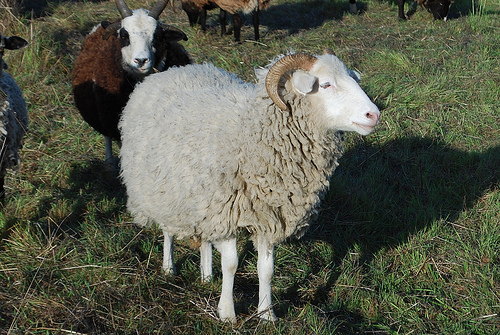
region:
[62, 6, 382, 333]
two sheep in a pasture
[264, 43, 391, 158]
the head of a sheep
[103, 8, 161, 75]
the head of a sheep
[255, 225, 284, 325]
the leg of a sheep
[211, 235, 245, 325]
the leg of a sheep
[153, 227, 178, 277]
the leg of a sheep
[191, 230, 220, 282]
the leg of a sheep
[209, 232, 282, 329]
the front legs of a sheep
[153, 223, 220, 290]
the rear legs of a sheep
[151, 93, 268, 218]
the fur of a sheep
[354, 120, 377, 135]
a rams mouth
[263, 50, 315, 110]
a single ram horn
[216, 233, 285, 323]
a pair of white front legs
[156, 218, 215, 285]
a pair of back legs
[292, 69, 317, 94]
a white ram ear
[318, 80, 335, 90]
a ram eye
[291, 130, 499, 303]
the shadow of a ram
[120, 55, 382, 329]
a white ram with a dirty coat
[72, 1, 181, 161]
a brown fluffy ram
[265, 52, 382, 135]
the head of a ram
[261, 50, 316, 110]
a single rams horn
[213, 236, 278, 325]
a white pair of front legs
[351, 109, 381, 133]
the nose and mouth of a ram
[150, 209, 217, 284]
a back pair of legs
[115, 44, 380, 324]
a white dirty ram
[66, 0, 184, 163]
a dark brown ram with a white head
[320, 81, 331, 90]
a rams eye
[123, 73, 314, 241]
the white coat of a ram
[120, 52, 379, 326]
white sheep with curved brown horns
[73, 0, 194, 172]
brown, black and white sheep with horns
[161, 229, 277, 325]
sheep's legs sticking out from wool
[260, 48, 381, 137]
ship's head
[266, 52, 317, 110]
brown sheep's horn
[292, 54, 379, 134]
sheep's face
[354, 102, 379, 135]
sheep's nose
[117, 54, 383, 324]
wooly sheep ready to be sheared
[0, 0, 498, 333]
flock of sheep in grassy field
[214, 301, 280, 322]
sheep hooves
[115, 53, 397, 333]
white sheep standing in the grass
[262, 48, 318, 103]
horn of the white sheep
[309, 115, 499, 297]
shadow of the white sheep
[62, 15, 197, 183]
brown sheep with white face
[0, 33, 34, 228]
sheep standing on the left side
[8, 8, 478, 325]
grass pasture the sheep are in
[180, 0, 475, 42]
black legs of sheep in the background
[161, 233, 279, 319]
white legs of sheep in the foreground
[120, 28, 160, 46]
brown markings on white face of sheep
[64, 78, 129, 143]
shadow on the brown and white sheep